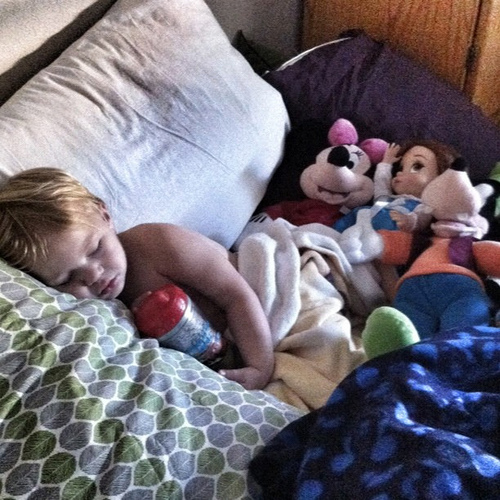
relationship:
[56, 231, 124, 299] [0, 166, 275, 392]
face of child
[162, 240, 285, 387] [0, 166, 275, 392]
arm of child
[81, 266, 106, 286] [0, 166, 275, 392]
nose of child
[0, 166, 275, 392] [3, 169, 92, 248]
child has hair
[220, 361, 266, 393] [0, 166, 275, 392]
hand of child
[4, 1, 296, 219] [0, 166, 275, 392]
pillow under child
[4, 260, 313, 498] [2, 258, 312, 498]
sheet has design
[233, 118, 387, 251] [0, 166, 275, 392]
character laying beside child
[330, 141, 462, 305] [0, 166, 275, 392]
character laying beside child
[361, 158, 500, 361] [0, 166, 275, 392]
character laying beside child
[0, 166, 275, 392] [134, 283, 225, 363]
child holding bottle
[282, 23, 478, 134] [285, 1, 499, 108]
pillow sitting next to wall